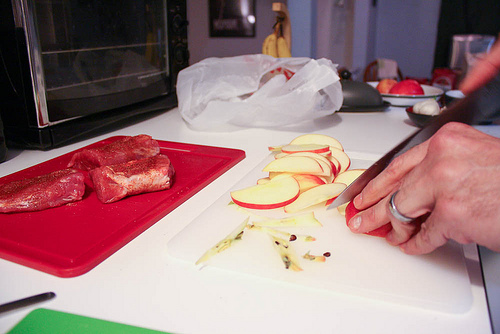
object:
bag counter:
[176, 54, 344, 133]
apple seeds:
[194, 215, 330, 272]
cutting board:
[163, 141, 474, 314]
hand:
[347, 121, 499, 256]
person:
[348, 36, 500, 255]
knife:
[325, 67, 498, 210]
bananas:
[261, 13, 292, 59]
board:
[168, 144, 473, 314]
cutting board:
[0, 135, 247, 279]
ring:
[388, 190, 418, 223]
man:
[348, 41, 500, 257]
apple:
[231, 175, 301, 210]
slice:
[229, 177, 300, 209]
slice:
[261, 156, 324, 173]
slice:
[281, 180, 348, 215]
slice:
[280, 143, 332, 154]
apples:
[226, 135, 377, 215]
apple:
[229, 134, 394, 239]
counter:
[0, 81, 498, 334]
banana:
[276, 33, 292, 59]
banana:
[261, 32, 279, 59]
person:
[347, 121, 500, 256]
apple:
[192, 134, 429, 273]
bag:
[176, 54, 344, 131]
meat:
[64, 133, 177, 203]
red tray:
[1, 134, 246, 278]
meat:
[0, 169, 89, 214]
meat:
[0, 133, 177, 216]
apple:
[283, 182, 349, 213]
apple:
[260, 154, 325, 174]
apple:
[264, 142, 329, 154]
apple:
[345, 199, 392, 239]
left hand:
[348, 121, 500, 255]